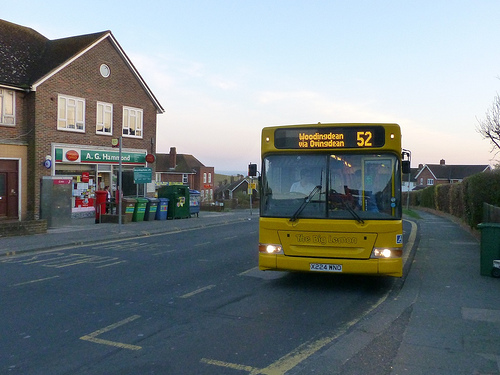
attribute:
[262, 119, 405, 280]
bus — yellow